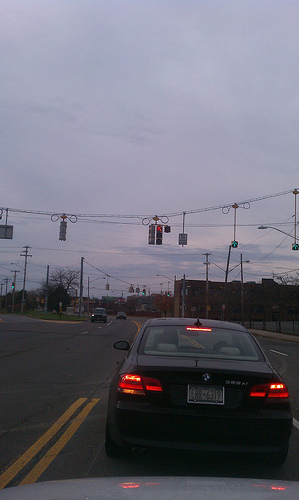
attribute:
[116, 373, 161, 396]
tail light — red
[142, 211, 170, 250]
traffic signal — large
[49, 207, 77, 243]
traffic signal — large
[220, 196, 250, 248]
traffic signal — large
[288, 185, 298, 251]
traffic signal — large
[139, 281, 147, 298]
traffic signal — large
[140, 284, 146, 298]
traffic signal — large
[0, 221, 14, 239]
signal — large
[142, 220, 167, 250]
traffic signal — large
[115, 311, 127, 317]
car — small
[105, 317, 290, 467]
car — black, small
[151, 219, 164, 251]
signal — traffic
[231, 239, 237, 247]
arrow — green, lit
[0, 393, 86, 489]
lines — yellow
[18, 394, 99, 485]
lines — yellow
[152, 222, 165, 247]
traffic signal — large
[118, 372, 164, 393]
light — on a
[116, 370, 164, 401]
light — rear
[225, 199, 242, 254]
signal — large